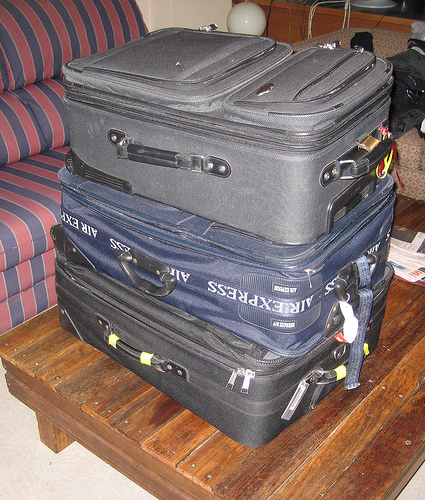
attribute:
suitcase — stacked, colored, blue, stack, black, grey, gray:
[27, 16, 404, 440]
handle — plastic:
[118, 144, 213, 188]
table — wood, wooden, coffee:
[31, 344, 159, 487]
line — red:
[28, 315, 62, 373]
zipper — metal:
[297, 245, 351, 295]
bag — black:
[143, 180, 405, 369]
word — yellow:
[368, 134, 405, 186]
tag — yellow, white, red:
[353, 130, 404, 192]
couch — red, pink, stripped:
[2, 8, 127, 85]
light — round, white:
[221, 4, 277, 52]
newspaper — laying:
[371, 221, 422, 293]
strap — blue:
[334, 283, 375, 389]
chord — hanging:
[302, 15, 375, 30]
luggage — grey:
[72, 19, 364, 242]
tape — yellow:
[337, 139, 404, 212]